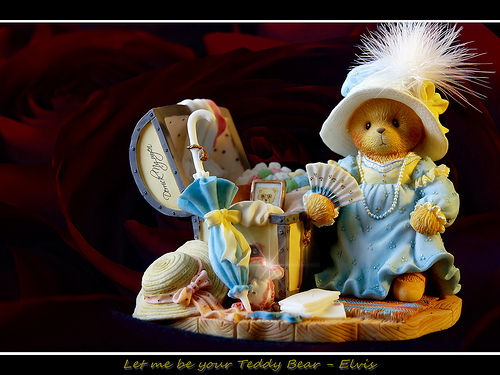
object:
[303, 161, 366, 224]
fan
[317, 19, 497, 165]
hat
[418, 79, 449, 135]
yellow bow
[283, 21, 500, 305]
teddy bear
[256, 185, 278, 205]
bear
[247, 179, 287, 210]
framed photo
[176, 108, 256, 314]
umbrella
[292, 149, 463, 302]
dress